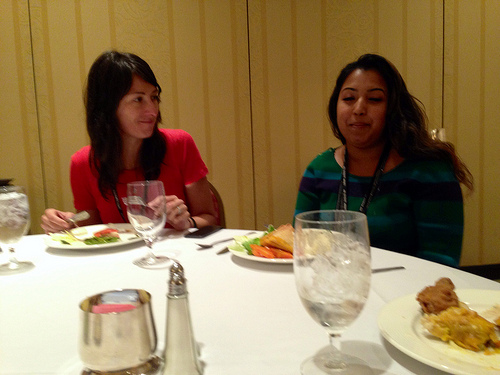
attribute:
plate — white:
[227, 245, 291, 279]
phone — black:
[183, 218, 225, 250]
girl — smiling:
[57, 41, 213, 245]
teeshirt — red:
[65, 150, 225, 253]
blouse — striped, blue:
[262, 143, 474, 266]